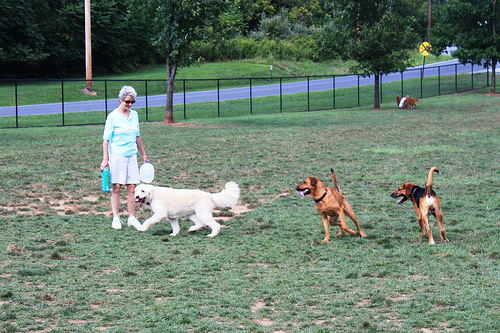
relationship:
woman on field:
[98, 85, 149, 230] [2, 85, 499, 332]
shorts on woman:
[104, 152, 142, 189] [98, 85, 149, 230]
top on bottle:
[143, 160, 146, 161] [139, 157, 155, 182]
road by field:
[0, 55, 498, 115] [2, 85, 499, 332]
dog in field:
[132, 179, 241, 238] [2, 85, 499, 332]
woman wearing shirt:
[98, 85, 149, 230] [92, 107, 160, 162]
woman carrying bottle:
[98, 83, 148, 230] [138, 163, 156, 184]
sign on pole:
[417, 38, 435, 59] [416, 55, 431, 80]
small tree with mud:
[138, 0, 198, 132] [164, 112, 173, 124]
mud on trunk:
[164, 112, 173, 124] [165, 80, 177, 127]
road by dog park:
[0, 54, 499, 118] [1, 80, 494, 331]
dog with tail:
[132, 179, 241, 238] [210, 179, 242, 209]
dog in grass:
[132, 179, 241, 238] [0, 84, 499, 331]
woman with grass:
[98, 85, 149, 230] [0, 85, 499, 331]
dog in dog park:
[132, 181, 240, 238] [0, 86, 499, 332]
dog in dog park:
[291, 158, 373, 249] [0, 86, 499, 332]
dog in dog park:
[387, 161, 454, 244] [0, 86, 499, 332]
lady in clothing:
[91, 73, 166, 224] [101, 110, 144, 186]